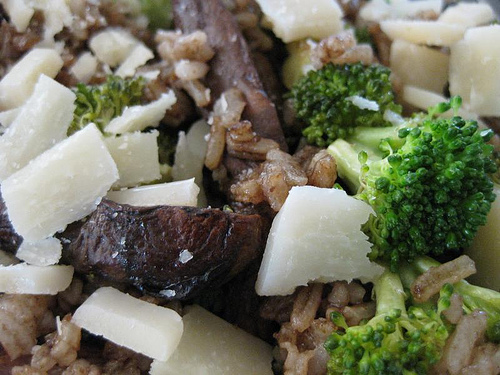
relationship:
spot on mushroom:
[174, 248, 193, 264] [81, 207, 243, 300]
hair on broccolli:
[321, 302, 342, 319] [71, 59, 497, 373]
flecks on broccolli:
[347, 80, 412, 135] [282, 59, 499, 249]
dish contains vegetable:
[39, 51, 471, 349] [346, 122, 474, 247]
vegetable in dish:
[253, 186, 385, 301] [3, 1, 495, 374]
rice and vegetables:
[170, 84, 287, 188] [4, 4, 497, 373]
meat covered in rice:
[180, 2, 282, 122] [165, 34, 223, 97]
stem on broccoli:
[330, 135, 379, 178] [333, 123, 480, 188]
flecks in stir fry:
[347, 80, 412, 135] [0, 0, 500, 372]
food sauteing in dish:
[0, 1, 484, 371] [3, 1, 495, 374]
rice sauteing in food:
[306, 28, 372, 68] [0, 1, 484, 371]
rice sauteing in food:
[155, 27, 212, 106] [0, 1, 484, 371]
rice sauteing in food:
[203, 88, 335, 208] [0, 1, 484, 371]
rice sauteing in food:
[437, 293, 497, 374] [0, 1, 484, 371]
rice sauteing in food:
[410, 251, 476, 300] [0, 1, 484, 371]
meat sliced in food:
[180, 2, 282, 122] [0, 1, 484, 371]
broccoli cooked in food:
[261, 55, 491, 374] [0, 1, 484, 371]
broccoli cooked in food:
[261, 55, 498, 375] [0, 1, 484, 371]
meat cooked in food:
[180, 2, 282, 122] [0, 1, 484, 371]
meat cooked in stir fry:
[180, 2, 282, 122] [0, 0, 500, 372]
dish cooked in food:
[39, 51, 471, 349] [0, 1, 484, 371]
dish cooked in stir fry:
[39, 51, 471, 349] [0, 0, 500, 372]